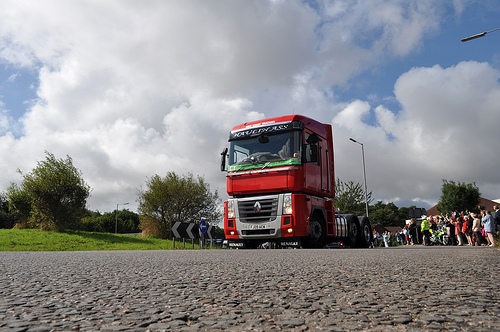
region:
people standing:
[427, 213, 492, 243]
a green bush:
[28, 158, 87, 224]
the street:
[3, 245, 488, 330]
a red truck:
[226, 128, 336, 240]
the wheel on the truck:
[310, 215, 326, 240]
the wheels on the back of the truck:
[350, 212, 370, 233]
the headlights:
[281, 198, 296, 215]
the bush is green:
[437, 185, 477, 207]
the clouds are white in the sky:
[33, 7, 306, 114]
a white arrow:
[194, 222, 209, 233]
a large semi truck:
[216, 105, 341, 262]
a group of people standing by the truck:
[371, 202, 498, 252]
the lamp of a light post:
[462, 27, 498, 40]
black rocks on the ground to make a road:
[2, 235, 499, 329]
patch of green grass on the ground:
[0, 214, 190, 255]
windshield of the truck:
[222, 128, 307, 163]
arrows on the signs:
[167, 218, 221, 248]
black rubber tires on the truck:
[299, 211, 373, 248]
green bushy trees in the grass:
[10, 151, 226, 246]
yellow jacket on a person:
[417, 218, 434, 230]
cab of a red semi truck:
[223, 108, 337, 248]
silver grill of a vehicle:
[233, 199, 277, 226]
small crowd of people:
[407, 209, 498, 246]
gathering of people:
[401, 208, 496, 252]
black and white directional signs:
[175, 219, 219, 241]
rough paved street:
[115, 249, 405, 330]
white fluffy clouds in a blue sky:
[11, 36, 205, 164]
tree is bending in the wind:
[16, 145, 92, 231]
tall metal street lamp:
[342, 132, 377, 217]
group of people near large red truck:
[212, 90, 492, 290]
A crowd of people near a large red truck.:
[225, 115, 496, 246]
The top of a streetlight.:
[450, 27, 495, 42]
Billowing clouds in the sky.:
[6, 17, 496, 209]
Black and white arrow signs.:
[165, 212, 215, 242]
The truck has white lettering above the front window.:
[221, 117, 286, 141]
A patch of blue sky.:
[335, 22, 490, 108]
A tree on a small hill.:
[15, 150, 90, 225]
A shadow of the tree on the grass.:
[76, 215, 153, 245]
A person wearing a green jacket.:
[415, 212, 431, 242]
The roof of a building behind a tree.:
[418, 188, 495, 213]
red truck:
[221, 115, 351, 241]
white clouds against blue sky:
[12, 15, 79, 72]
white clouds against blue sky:
[0, 67, 77, 130]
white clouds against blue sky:
[123, 28, 181, 58]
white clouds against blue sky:
[132, 74, 209, 119]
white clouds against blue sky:
[248, 20, 337, 77]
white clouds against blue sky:
[323, 63, 411, 103]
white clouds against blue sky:
[355, 95, 442, 166]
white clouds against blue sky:
[365, 2, 411, 57]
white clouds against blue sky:
[416, 36, 464, 78]